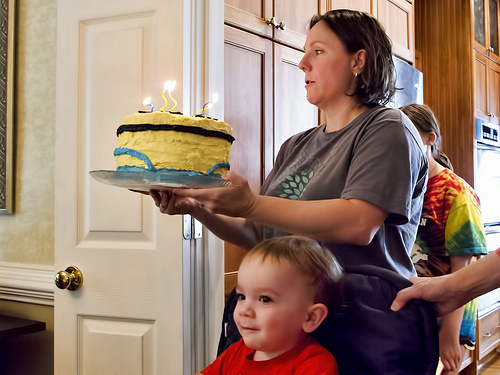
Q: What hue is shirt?
A: Gray.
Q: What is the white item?
A: Door.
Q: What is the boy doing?
A: Sitting.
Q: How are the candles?
A: Lit.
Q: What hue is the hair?
A: Brown.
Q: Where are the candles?
A: On cake.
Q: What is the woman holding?
A: Cake.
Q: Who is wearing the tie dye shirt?
A: Girl.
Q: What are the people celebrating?
A: A birthday.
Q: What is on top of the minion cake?
A: Candles.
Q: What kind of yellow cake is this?
A: Birthday.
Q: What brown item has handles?
A: Cupboard.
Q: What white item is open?
A: Door.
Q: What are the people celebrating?
A: A birthday.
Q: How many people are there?
A: Four.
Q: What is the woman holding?
A: A cake.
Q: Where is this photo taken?
A: In a kitchen.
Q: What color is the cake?
A: Blue, yellow and black.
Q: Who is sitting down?
A: A little boy.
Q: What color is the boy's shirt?
A: Red.